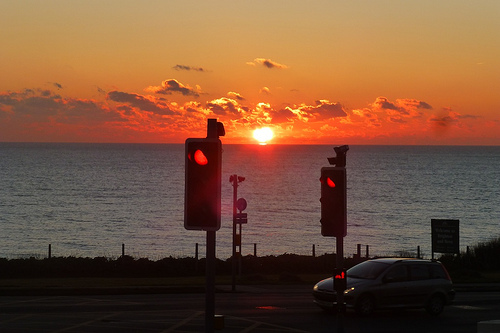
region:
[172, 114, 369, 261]
Traffic lights by the road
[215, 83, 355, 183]
Sun is setting by the ocean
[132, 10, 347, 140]
The sky is orange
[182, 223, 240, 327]
metal under the light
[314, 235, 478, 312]
Car driving down the road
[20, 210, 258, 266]
Fence by the ocean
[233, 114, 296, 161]
Sun in the sky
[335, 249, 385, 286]
Windshield on the car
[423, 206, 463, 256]
Sign by the beach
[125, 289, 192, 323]
White paint on the road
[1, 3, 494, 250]
Orange and red sunset over water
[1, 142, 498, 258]
Large body of water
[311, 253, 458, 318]
Grey SUV with headlights on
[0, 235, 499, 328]
Road along the water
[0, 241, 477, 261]
Series of fence posts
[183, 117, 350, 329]
Two traffic lights beside a road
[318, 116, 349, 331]
A red traffic signal with a do not walk signal below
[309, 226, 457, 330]
Car driving along the water's edge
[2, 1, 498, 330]
Shoreline scene in the evening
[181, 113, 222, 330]
Metal pole holding a traffic light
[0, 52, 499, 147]
the clouds in the sky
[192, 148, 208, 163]
the red traffic light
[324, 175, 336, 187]
the red traffic light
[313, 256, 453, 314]
the car on the street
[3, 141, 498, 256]
the body of water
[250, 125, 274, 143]
the sun in the sky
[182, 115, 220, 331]
the traffic light on the pole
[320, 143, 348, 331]
the traffic light on the pole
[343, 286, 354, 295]
the light on the car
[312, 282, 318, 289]
the light on the car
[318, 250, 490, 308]
a car driving pass the ocean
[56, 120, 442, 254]
the ocean located near a road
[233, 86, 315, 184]
the sun is setting inside the ocean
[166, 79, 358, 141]
clouds are luminated by the sun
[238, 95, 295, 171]
the sun luminating the clouds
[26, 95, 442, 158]
the sky displaying various of colors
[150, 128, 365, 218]
traffic lights installed in front of the ocean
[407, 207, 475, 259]
a sign displayed near a road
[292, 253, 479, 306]
a car driving down a road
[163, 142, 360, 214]
red light shinging from the traffic lights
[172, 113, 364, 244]
two traffic lights are in this area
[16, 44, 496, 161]
the sunset is in the background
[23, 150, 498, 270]
the ocean can be seen in the distance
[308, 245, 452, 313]
a van is parked in the lot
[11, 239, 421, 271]
posts run along the edge of the lot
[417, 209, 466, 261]
a road sign is behind the van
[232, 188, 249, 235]
a few road signs are in the background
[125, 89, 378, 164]
the sunset is orange in color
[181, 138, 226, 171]
the traffic light displays the red light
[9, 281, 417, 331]
a portion of the road